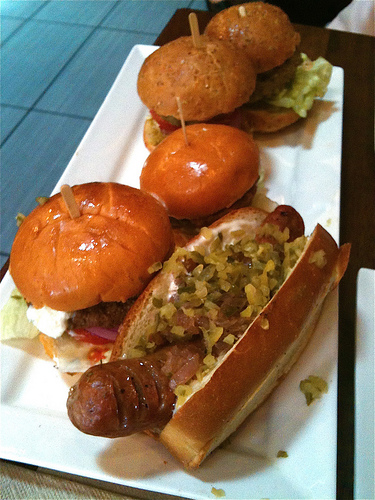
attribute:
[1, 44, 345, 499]
platter — white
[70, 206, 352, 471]
hotdog — slit, brown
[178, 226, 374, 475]
bread — rectangular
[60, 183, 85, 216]
stick — flat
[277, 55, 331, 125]
lettuce — green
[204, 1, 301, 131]
bread — curved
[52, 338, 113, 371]
cheese — cube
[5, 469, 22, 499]
lines — dark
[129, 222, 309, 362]
relish — green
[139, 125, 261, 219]
bun — greasy, brown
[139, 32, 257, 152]
crust — brown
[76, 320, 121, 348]
onion — purple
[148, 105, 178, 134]
tomato — red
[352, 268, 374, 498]
plate — white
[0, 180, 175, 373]
food — sitting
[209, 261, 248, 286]
pickles — green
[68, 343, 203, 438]
sausage — roasted